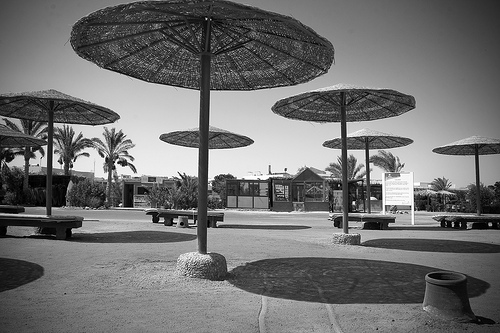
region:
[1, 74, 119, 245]
Bench under an umbrella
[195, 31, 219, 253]
Pole on a large umbrella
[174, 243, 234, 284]
Base of an umbrella mounted on concrete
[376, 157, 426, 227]
White sign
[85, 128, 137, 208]
Palm tree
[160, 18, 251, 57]
Supports underneath an umbrella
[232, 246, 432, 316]
Shadow of an umbrella on the ground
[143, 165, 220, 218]
Bushes near sitting area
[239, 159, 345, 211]
Building near sitting area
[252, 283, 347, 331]
Lines on the ground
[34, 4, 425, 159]
The umbrellas are open.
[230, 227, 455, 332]
The umbrellas are casting shadows.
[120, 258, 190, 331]
The ground is concrete.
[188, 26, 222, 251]
The pole is brown.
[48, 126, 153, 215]
The trees are palm trees.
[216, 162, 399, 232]
THe building is far away.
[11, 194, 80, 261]
The bench is concrete.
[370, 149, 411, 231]
The sign is white.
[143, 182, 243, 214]
The bush is leafy.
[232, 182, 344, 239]
The building has a white sign.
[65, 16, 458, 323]
Umbrellas on the patio.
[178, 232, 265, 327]
Base of the umbrella.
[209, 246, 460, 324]
Shadow on the patio.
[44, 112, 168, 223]
Palm trees in the background.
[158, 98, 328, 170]
Open umbrella in the air.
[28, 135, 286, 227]
Buildings in the background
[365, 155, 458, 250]
Sign on the patio.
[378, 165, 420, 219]
Sign in the background.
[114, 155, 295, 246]
Trees and buildings in the background.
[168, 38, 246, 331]
Pole of the umbrella.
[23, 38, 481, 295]
black and white picture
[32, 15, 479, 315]
picture taken outdoors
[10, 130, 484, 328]
picture taken during the day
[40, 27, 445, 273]
umbrellas around the area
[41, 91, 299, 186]
palm trees behind the umbrellas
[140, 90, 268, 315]
the umbrella pole is cemented to the ground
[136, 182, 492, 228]
tables near the umbrellas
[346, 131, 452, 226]
A sign is behind the umbrella and bench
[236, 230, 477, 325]
the shadow of the umbrellas on the ground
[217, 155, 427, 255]
a building behind all of the umbrellas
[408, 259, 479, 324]
small black trash bin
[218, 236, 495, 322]
shadow cast by umbrella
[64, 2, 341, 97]
canopy of shade umbrella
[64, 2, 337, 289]
tall metal shade umbrella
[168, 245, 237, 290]
concrete stand for umbrella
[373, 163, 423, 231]
white sign with writing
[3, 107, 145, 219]
line of tall palm trees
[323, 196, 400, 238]
small stone park bench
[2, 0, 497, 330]
large group of umbrellas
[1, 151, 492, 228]
line of buildings behind a park